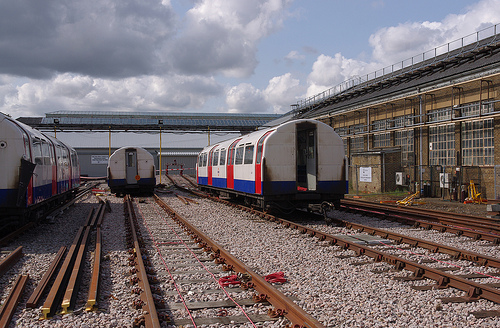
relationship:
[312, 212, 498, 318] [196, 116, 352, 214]
railroad tracks near train car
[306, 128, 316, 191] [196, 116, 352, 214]
door of train car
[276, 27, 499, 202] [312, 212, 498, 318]
building beside railroad tracks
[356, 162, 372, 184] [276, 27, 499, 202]
sign outside building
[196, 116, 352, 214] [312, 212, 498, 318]
train car above railroad tracks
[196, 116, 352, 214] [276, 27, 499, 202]
train car near building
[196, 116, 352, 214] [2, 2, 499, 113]
train car under sky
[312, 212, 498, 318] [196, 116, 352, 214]
railroad tracks under train car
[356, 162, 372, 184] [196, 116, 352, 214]
sign near train car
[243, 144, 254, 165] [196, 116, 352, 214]
window of train car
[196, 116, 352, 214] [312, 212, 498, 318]
train car sitting on railroad tracks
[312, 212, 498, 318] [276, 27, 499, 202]
railroad tracks near building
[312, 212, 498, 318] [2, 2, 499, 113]
railroad tracks under sky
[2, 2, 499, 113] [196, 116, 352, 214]
sky over train car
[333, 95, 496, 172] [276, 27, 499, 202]
windows of building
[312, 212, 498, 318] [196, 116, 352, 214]
railroad tracks for train car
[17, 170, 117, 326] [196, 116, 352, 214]
railing sitting beside train car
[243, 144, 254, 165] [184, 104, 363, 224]
window on train